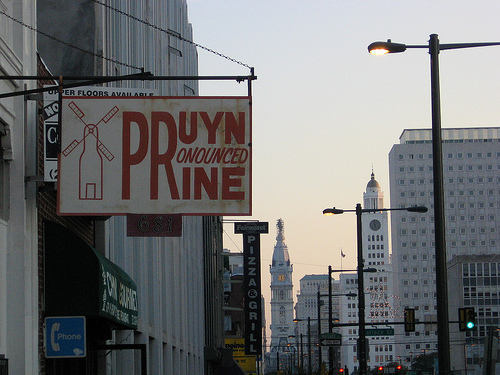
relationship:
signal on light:
[458, 307, 476, 331] [465, 322, 475, 330]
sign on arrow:
[313, 330, 344, 350] [316, 337, 343, 348]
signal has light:
[457, 306, 474, 333] [465, 322, 472, 329]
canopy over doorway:
[44, 218, 141, 332] [38, 309, 145, 374]